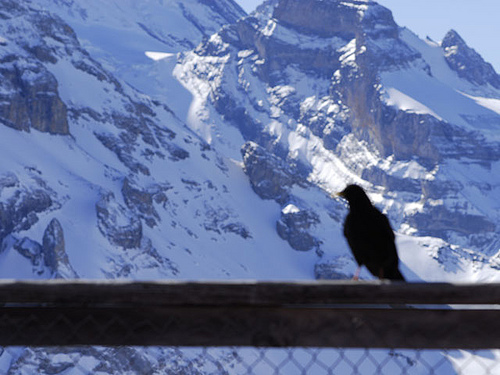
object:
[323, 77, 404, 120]
rock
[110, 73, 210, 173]
shadow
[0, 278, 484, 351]
railing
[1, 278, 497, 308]
wood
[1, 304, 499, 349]
wood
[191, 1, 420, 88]
peak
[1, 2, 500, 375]
mountain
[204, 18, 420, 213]
layer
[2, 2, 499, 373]
mountainside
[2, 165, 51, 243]
outcrop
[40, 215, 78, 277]
outcrop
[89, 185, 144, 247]
outcrop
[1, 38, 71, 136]
outcrop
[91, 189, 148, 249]
outcrop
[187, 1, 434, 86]
mountain tip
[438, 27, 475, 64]
mountain tip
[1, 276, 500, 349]
pole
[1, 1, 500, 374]
snow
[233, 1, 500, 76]
sky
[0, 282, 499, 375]
fence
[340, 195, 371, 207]
neck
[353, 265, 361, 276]
leg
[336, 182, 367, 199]
head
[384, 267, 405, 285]
tail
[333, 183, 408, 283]
bird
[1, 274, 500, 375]
ledge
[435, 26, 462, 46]
peak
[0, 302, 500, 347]
support beam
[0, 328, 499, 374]
wire fencing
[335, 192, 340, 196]
beak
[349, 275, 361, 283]
foot